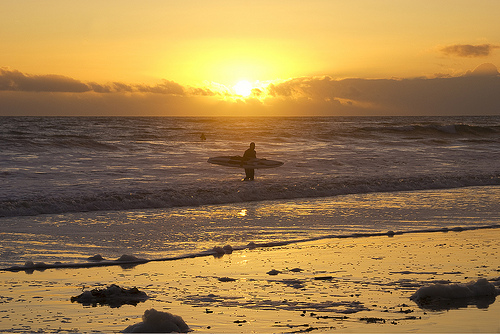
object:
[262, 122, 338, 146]
ripples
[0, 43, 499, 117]
clouds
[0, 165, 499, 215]
surf boarder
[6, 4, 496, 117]
thehorizon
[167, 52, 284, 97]
sun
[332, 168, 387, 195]
wave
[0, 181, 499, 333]
beach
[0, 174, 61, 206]
ripples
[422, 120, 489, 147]
ripples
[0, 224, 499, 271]
foam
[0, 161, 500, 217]
riddles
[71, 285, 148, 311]
rock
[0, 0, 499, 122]
sky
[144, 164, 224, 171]
ripple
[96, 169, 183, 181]
ripple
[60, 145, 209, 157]
ripple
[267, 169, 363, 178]
ripple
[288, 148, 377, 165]
ripple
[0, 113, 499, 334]
water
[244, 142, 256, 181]
man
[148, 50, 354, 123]
sunset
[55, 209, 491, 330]
sand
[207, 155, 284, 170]
surfboard